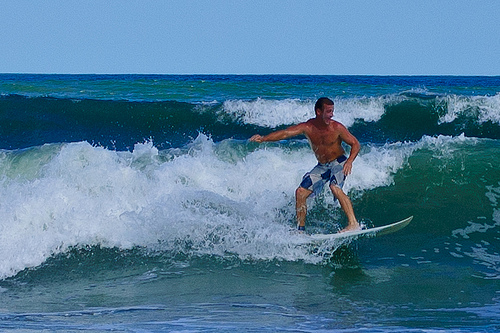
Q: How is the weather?
A: It is cloudless.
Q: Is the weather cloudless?
A: Yes, it is cloudless.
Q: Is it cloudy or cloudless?
A: It is cloudless.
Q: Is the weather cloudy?
A: No, it is cloudless.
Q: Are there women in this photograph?
A: No, there are no women.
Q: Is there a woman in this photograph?
A: No, there are no women.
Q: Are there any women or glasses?
A: No, there are no women or glasses.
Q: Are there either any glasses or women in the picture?
A: No, there are no women or glasses.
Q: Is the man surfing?
A: Yes, the man is surfing.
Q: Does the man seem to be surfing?
A: Yes, the man is surfing.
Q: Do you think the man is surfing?
A: Yes, the man is surfing.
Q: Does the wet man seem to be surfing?
A: Yes, the man is surfing.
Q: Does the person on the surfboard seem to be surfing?
A: Yes, the man is surfing.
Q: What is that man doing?
A: The man is surfing.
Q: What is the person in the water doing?
A: The man is surfing.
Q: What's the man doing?
A: The man is surfing.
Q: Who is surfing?
A: The man is surfing.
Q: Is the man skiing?
A: No, the man is surfing.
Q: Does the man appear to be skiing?
A: No, the man is surfing.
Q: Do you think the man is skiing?
A: No, the man is surfing.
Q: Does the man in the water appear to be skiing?
A: No, the man is surfing.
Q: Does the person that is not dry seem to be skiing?
A: No, the man is surfing.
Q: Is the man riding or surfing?
A: The man is surfing.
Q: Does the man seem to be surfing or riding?
A: The man is surfing.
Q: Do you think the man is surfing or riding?
A: The man is surfing.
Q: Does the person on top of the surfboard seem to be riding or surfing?
A: The man is surfing.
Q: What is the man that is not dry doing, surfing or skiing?
A: The man is surfing.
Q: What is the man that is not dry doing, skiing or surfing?
A: The man is surfing.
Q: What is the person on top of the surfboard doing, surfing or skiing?
A: The man is surfing.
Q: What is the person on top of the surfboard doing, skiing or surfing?
A: The man is surfing.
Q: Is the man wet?
A: Yes, the man is wet.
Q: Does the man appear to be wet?
A: Yes, the man is wet.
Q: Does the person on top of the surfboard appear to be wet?
A: Yes, the man is wet.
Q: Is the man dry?
A: No, the man is wet.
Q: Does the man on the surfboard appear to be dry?
A: No, the man is wet.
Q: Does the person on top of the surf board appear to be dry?
A: No, the man is wet.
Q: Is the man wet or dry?
A: The man is wet.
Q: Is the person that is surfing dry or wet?
A: The man is wet.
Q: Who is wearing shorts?
A: The man is wearing shorts.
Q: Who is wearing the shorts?
A: The man is wearing shorts.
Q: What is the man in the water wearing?
A: The man is wearing shorts.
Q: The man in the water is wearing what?
A: The man is wearing shorts.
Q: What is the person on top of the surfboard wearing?
A: The man is wearing shorts.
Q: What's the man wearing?
A: The man is wearing shorts.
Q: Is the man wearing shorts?
A: Yes, the man is wearing shorts.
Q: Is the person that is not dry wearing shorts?
A: Yes, the man is wearing shorts.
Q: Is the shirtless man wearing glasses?
A: No, the man is wearing shorts.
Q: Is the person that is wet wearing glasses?
A: No, the man is wearing shorts.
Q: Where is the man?
A: The man is in the water.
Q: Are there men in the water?
A: Yes, there is a man in the water.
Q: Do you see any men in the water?
A: Yes, there is a man in the water.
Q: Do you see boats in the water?
A: No, there is a man in the water.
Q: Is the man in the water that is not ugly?
A: Yes, the man is in the water.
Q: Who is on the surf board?
A: The man is on the surf board.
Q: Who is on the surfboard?
A: The man is on the surf board.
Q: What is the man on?
A: The man is on the surfboard.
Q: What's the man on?
A: The man is on the surfboard.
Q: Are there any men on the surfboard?
A: Yes, there is a man on the surfboard.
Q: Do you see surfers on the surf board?
A: No, there is a man on the surf board.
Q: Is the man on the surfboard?
A: Yes, the man is on the surfboard.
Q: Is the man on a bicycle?
A: No, the man is on the surfboard.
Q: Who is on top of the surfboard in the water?
A: The man is on top of the surfboard.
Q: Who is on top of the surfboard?
A: The man is on top of the surfboard.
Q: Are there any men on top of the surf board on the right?
A: Yes, there is a man on top of the surfboard.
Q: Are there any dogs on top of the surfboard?
A: No, there is a man on top of the surfboard.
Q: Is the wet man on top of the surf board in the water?
A: Yes, the man is on top of the surfboard.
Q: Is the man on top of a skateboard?
A: No, the man is on top of the surfboard.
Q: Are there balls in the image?
A: No, there are no balls.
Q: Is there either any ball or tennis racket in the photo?
A: No, there are no balls or rackets.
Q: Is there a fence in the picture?
A: No, there are no fences.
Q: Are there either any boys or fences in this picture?
A: No, there are no fences or boys.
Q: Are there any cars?
A: No, there are no cars.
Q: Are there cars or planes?
A: No, there are no cars or planes.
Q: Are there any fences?
A: No, there are no fences.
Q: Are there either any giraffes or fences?
A: No, there are no fences or giraffes.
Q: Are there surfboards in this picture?
A: Yes, there is a surfboard.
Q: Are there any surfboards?
A: Yes, there is a surfboard.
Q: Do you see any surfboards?
A: Yes, there is a surfboard.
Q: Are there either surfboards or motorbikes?
A: Yes, there is a surfboard.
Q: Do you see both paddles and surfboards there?
A: No, there is a surfboard but no paddles.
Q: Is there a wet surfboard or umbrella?
A: Yes, there is a wet surfboard.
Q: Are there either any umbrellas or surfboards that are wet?
A: Yes, the surfboard is wet.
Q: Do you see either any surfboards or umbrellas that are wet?
A: Yes, the surfboard is wet.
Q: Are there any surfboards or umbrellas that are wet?
A: Yes, the surfboard is wet.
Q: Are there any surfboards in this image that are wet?
A: Yes, there is a wet surfboard.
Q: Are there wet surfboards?
A: Yes, there is a wet surfboard.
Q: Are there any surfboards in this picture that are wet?
A: Yes, there is a surfboard that is wet.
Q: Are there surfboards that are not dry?
A: Yes, there is a wet surfboard.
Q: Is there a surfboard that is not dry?
A: Yes, there is a wet surfboard.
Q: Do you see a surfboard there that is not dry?
A: Yes, there is a wet surfboard.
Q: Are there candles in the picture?
A: No, there are no candles.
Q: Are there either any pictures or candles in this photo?
A: No, there are no candles or pictures.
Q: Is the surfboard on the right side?
A: Yes, the surfboard is on the right of the image.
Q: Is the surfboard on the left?
A: No, the surfboard is on the right of the image.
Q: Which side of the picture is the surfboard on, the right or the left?
A: The surfboard is on the right of the image.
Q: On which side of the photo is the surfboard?
A: The surfboard is on the right of the image.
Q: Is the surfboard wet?
A: Yes, the surfboard is wet.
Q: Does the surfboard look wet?
A: Yes, the surfboard is wet.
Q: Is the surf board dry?
A: No, the surf board is wet.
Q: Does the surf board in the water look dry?
A: No, the surfboard is wet.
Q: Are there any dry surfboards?
A: No, there is a surfboard but it is wet.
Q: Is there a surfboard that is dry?
A: No, there is a surfboard but it is wet.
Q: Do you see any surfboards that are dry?
A: No, there is a surfboard but it is wet.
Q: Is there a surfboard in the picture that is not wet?
A: No, there is a surfboard but it is wet.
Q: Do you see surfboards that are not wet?
A: No, there is a surfboard but it is wet.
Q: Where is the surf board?
A: The surf board is in the water.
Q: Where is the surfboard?
A: The surf board is in the water.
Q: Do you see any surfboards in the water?
A: Yes, there is a surfboard in the water.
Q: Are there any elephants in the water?
A: No, there is a surfboard in the water.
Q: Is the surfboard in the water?
A: Yes, the surfboard is in the water.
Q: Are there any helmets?
A: No, there are no helmets.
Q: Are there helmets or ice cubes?
A: No, there are no helmets or ice cubes.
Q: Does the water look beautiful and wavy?
A: Yes, the water is beautiful and wavy.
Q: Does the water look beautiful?
A: Yes, the water is beautiful.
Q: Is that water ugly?
A: No, the water is beautiful.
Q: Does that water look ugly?
A: No, the water is beautiful.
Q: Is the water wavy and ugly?
A: No, the water is wavy but beautiful.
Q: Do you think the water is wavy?
A: Yes, the water is wavy.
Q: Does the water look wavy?
A: Yes, the water is wavy.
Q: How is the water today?
A: The water is wavy.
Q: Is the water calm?
A: No, the water is wavy.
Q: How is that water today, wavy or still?
A: The water is wavy.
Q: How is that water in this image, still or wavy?
A: The water is wavy.